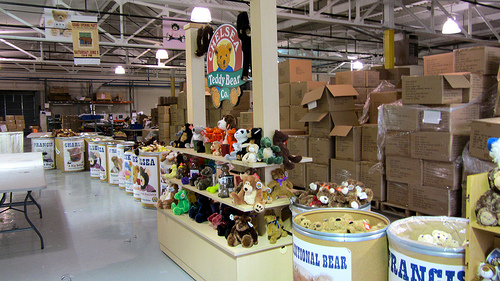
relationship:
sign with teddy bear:
[44, 7, 78, 40] [52, 10, 70, 35]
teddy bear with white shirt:
[52, 10, 70, 35] [54, 20, 68, 28]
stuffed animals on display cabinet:
[172, 120, 294, 241] [156, 141, 313, 280]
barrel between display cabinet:
[291, 189, 371, 219] [465, 170, 487, 278]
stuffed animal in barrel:
[305, 185, 332, 205] [289, 205, 388, 278]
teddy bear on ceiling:
[206, 42, 243, 106] [151, 2, 320, 21]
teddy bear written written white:
[206, 37, 241, 106] [206, 67, 243, 101]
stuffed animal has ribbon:
[265, 165, 295, 199] [274, 171, 296, 187]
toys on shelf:
[175, 121, 287, 234] [140, 110, 314, 247]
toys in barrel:
[295, 213, 467, 251] [289, 207, 391, 280]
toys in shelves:
[162, 116, 301, 249] [253, 171, 301, 225]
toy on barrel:
[307, 186, 335, 207] [285, 186, 377, 226]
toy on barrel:
[297, 211, 311, 232] [285, 186, 377, 226]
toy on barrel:
[431, 226, 450, 247] [384, 214, 469, 278]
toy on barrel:
[414, 231, 437, 247] [384, 214, 469, 278]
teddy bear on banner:
[206, 42, 243, 106] [205, 23, 245, 107]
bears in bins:
[230, 127, 273, 182] [23, 123, 167, 205]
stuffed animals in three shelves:
[165, 121, 295, 255] [140, 130, 290, 277]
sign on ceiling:
[162, 17, 190, 51] [2, 2, 498, 75]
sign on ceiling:
[69, 12, 101, 65] [2, 2, 498, 75]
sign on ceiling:
[44, 3, 78, 40] [2, 2, 498, 75]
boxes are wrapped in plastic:
[374, 89, 479, 214] [371, 103, 421, 147]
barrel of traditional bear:
[289, 207, 391, 280] [340, 222, 351, 233]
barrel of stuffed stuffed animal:
[306, 199, 413, 280] [265, 165, 295, 199]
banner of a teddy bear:
[196, 23, 248, 107] [169, 188, 192, 215]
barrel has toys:
[269, 200, 411, 275] [294, 195, 381, 240]